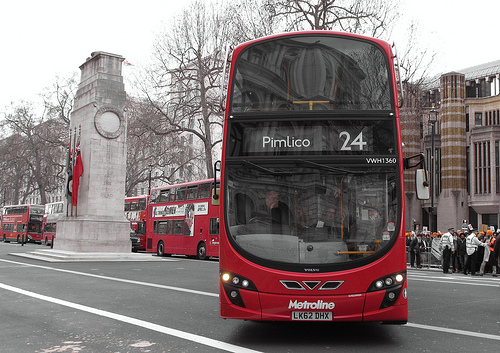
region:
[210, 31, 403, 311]
red bus turning on street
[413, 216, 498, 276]
people standing on sidewalk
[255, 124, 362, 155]
white letters and numbers on black background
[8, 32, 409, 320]
five red buses in a row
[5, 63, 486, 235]
row of buildings on sidewalk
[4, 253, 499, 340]
white lines painted on street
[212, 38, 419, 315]
red double decker bus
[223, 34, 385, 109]
second deck of red bus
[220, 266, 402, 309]
front lights of red bus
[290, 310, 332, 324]
white and black front license plate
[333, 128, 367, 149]
The number 24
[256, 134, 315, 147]
The word Pimlico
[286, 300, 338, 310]
The word Metroline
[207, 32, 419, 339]
A red bus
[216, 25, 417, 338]
A double decker bus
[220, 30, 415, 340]
A bus turning on the road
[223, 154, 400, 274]
A large windshield on the bus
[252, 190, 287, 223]
A male bus driver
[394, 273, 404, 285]
A headlight on the front of the bus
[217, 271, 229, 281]
A headlight on the front of the bus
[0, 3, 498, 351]
A view of a city street.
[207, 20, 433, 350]
The bus is red.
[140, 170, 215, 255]
A second red bus.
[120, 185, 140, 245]
A third bus is partially visible.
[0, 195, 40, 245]
A fourth bus in the distance.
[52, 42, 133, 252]
A monument made of stone.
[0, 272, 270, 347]
A white line painted on the street.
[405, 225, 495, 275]
A group of people.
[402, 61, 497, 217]
The building is brown.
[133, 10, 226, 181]
A tree without leaves.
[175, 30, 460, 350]
a bus on the road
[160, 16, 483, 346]
a red bus on the road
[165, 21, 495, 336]
a passenger bus on the raod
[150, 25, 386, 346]
a red passenger bus on the road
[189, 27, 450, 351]
a double decker bus on the road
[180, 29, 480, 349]
a bus on the street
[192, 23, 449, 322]
a red bus on the street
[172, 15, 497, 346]
a passenger bus on the street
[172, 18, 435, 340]
a red double decker bus on the street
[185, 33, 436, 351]
a double decker bus on the street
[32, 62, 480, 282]
This is an outdoor setting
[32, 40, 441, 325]
This is taken in a city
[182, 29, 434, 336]
This is a double decker bus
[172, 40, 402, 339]
This is a commuter bus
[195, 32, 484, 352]
The bus is red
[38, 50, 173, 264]
This is a pillar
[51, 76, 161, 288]
The pillar is gray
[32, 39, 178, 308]
The pillar is made of stone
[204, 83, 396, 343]
The window is reflected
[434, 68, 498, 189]
This column is brown